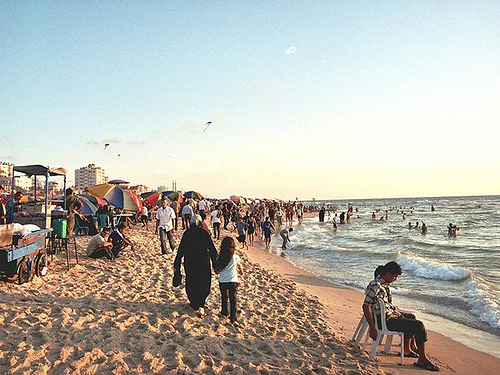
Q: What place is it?
A: It is a beach.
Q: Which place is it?
A: It is a beach.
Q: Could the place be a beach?
A: Yes, it is a beach.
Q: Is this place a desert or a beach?
A: It is a beach.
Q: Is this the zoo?
A: No, it is the beach.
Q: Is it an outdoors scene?
A: Yes, it is outdoors.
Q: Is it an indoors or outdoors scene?
A: It is outdoors.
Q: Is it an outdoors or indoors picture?
A: It is outdoors.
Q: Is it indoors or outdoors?
A: It is outdoors.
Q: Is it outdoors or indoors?
A: It is outdoors.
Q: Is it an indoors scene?
A: No, it is outdoors.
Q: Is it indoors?
A: No, it is outdoors.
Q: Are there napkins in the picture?
A: No, there are no napkins.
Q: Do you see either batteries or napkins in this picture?
A: No, there are no napkins or batteries.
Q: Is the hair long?
A: Yes, the hair is long.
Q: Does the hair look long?
A: Yes, the hair is long.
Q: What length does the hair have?
A: The hair has long length.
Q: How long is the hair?
A: The hair is long.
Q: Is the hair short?
A: No, the hair is long.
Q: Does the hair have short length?
A: No, the hair is long.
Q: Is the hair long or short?
A: The hair is long.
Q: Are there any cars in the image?
A: No, there are no cars.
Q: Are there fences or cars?
A: No, there are no cars or fences.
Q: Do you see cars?
A: No, there are no cars.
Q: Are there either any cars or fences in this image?
A: No, there are no cars or fences.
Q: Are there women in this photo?
A: Yes, there is a woman.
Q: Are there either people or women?
A: Yes, there is a woman.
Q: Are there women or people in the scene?
A: Yes, there is a woman.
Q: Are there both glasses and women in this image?
A: No, there is a woman but no glasses.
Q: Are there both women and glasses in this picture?
A: No, there is a woman but no glasses.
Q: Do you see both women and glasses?
A: No, there is a woman but no glasses.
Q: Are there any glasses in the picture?
A: No, there are no glasses.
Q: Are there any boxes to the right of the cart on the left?
A: No, there is a woman to the right of the cart.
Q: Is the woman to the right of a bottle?
A: No, the woman is to the right of the cart.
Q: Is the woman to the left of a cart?
A: No, the woman is to the right of a cart.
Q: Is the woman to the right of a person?
A: No, the woman is to the left of a person.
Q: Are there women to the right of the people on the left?
A: Yes, there is a woman to the right of the people.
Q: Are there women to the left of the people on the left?
A: No, the woman is to the right of the people.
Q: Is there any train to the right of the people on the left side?
A: No, there is a woman to the right of the people.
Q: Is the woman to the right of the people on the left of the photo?
A: Yes, the woman is to the right of the people.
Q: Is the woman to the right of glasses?
A: No, the woman is to the right of the people.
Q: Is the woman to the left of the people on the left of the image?
A: No, the woman is to the right of the people.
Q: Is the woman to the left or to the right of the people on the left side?
A: The woman is to the right of the people.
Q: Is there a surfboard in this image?
A: No, there are no surfboards.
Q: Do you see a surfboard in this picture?
A: No, there are no surfboards.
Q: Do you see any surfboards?
A: No, there are no surfboards.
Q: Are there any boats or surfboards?
A: No, there are no surfboards or boats.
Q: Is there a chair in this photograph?
A: Yes, there is a chair.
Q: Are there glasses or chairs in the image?
A: Yes, there is a chair.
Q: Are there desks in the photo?
A: No, there are no desks.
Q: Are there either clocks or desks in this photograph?
A: No, there are no desks or clocks.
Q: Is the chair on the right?
A: Yes, the chair is on the right of the image.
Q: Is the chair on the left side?
A: No, the chair is on the right of the image.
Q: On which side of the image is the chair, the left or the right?
A: The chair is on the right of the image.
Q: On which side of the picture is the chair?
A: The chair is on the right of the image.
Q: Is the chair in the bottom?
A: Yes, the chair is in the bottom of the image.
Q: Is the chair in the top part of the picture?
A: No, the chair is in the bottom of the image.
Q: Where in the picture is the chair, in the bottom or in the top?
A: The chair is in the bottom of the image.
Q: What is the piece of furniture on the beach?
A: The piece of furniture is a chair.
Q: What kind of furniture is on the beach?
A: The piece of furniture is a chair.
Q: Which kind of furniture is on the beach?
A: The piece of furniture is a chair.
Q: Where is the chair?
A: The chair is on the beach.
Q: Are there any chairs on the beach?
A: Yes, there is a chair on the beach.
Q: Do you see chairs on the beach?
A: Yes, there is a chair on the beach.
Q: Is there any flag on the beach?
A: No, there is a chair on the beach.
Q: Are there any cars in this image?
A: No, there are no cars.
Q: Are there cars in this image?
A: No, there are no cars.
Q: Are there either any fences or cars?
A: No, there are no cars or fences.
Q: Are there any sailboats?
A: No, there are no sailboats.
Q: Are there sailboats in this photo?
A: No, there are no sailboats.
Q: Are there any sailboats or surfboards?
A: No, there are no sailboats or surfboards.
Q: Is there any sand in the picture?
A: Yes, there is sand.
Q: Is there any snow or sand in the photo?
A: Yes, there is sand.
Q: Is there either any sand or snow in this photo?
A: Yes, there is sand.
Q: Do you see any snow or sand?
A: Yes, there is sand.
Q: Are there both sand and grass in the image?
A: No, there is sand but no grass.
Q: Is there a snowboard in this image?
A: No, there are no snowboards.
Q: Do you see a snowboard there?
A: No, there are no snowboards.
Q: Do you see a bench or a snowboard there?
A: No, there are no snowboards or benches.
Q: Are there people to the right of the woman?
A: Yes, there are people to the right of the woman.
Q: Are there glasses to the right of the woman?
A: No, there are people to the right of the woman.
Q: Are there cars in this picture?
A: No, there are no cars.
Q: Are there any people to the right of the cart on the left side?
A: Yes, there are people to the right of the cart.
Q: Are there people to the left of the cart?
A: No, the people are to the right of the cart.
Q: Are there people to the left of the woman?
A: Yes, there are people to the left of the woman.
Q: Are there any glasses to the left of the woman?
A: No, there are people to the left of the woman.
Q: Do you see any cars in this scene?
A: No, there are no cars.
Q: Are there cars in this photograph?
A: No, there are no cars.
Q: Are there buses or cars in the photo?
A: No, there are no cars or buses.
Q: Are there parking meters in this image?
A: No, there are no parking meters.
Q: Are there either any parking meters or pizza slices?
A: No, there are no parking meters or pizza slices.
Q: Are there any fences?
A: No, there are no fences.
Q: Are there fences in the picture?
A: No, there are no fences.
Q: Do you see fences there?
A: No, there are no fences.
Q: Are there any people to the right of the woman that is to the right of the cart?
A: Yes, there are people to the right of the woman.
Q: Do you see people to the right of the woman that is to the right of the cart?
A: Yes, there are people to the right of the woman.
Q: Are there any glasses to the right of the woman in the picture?
A: No, there are people to the right of the woman.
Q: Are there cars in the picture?
A: No, there are no cars.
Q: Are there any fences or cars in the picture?
A: No, there are no cars or fences.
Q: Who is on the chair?
A: The people are on the chair.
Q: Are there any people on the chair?
A: Yes, there are people on the chair.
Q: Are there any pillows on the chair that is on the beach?
A: No, there are people on the chair.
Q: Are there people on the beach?
A: Yes, there are people on the beach.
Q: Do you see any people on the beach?
A: Yes, there are people on the beach.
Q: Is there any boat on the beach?
A: No, there are people on the beach.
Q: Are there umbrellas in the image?
A: Yes, there is an umbrella.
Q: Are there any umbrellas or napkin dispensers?
A: Yes, there is an umbrella.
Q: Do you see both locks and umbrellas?
A: No, there is an umbrella but no locks.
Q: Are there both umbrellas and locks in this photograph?
A: No, there is an umbrella but no locks.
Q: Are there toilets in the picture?
A: No, there are no toilets.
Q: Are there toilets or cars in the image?
A: No, there are no toilets or cars.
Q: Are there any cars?
A: No, there are no cars.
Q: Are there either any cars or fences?
A: No, there are no cars or fences.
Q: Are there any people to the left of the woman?
A: Yes, there are people to the left of the woman.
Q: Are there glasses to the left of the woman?
A: No, there are people to the left of the woman.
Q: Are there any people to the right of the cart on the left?
A: Yes, there are people to the right of the cart.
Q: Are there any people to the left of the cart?
A: No, the people are to the right of the cart.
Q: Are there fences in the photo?
A: No, there are no fences.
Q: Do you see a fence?
A: No, there are no fences.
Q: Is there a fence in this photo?
A: No, there are no fences.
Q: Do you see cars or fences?
A: No, there are no fences or cars.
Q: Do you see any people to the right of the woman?
A: Yes, there are people to the right of the woman.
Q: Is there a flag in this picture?
A: No, there are no flags.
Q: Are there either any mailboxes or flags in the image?
A: No, there are no flags or mailboxes.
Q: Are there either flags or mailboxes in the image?
A: No, there are no flags or mailboxes.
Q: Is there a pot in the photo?
A: No, there are no pots.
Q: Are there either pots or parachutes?
A: No, there are no pots or parachutes.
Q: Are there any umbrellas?
A: Yes, there is an umbrella.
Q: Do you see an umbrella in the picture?
A: Yes, there is an umbrella.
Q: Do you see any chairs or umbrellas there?
A: Yes, there is an umbrella.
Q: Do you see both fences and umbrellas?
A: No, there is an umbrella but no fences.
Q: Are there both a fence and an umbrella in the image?
A: No, there is an umbrella but no fences.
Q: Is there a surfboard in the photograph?
A: No, there are no surfboards.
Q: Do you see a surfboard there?
A: No, there are no surfboards.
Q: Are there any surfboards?
A: No, there are no surfboards.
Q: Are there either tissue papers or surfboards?
A: No, there are no surfboards or tissue papers.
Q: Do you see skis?
A: No, there are no skis.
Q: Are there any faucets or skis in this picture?
A: No, there are no skis or faucets.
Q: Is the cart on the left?
A: Yes, the cart is on the left of the image.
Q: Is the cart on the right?
A: No, the cart is on the left of the image.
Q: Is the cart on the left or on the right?
A: The cart is on the left of the image.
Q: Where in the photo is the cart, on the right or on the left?
A: The cart is on the left of the image.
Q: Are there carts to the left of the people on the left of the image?
A: Yes, there is a cart to the left of the people.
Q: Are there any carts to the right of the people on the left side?
A: No, the cart is to the left of the people.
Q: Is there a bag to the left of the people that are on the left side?
A: No, there is a cart to the left of the people.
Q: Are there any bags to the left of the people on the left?
A: No, there is a cart to the left of the people.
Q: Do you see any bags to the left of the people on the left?
A: No, there is a cart to the left of the people.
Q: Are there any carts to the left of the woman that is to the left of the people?
A: Yes, there is a cart to the left of the woman.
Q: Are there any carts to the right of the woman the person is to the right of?
A: No, the cart is to the left of the woman.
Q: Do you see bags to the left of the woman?
A: No, there is a cart to the left of the woman.